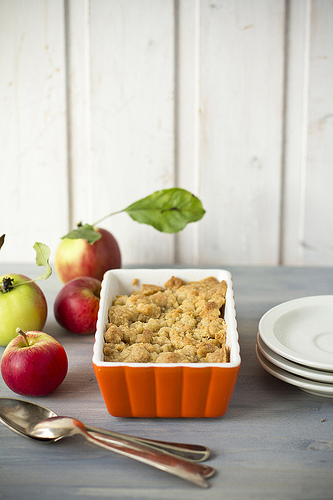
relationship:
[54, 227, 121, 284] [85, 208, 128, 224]
apple with stem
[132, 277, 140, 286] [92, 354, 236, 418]
crumb to side of dish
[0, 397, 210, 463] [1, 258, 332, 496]
spoon on counter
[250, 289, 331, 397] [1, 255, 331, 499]
saucers on table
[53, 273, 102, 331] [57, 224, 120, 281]
apple on apple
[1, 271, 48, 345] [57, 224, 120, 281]
apple on apple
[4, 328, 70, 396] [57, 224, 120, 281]
apple on apple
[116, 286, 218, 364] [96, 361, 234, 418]
apple crisp in dish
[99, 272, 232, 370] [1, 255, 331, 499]
dessert on table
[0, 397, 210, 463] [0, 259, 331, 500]
spoon on table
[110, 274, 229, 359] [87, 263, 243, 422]
food in pan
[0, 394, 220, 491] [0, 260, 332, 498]
spoon lying on ground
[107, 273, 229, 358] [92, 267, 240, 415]
oatmeal in bowl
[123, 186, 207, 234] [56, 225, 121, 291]
leaves sticking out of fruit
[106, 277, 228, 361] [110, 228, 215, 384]
breakfast in dish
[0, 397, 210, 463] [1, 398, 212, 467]
spoon resting inside spoon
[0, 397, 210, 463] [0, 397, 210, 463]
spoon on top spoon